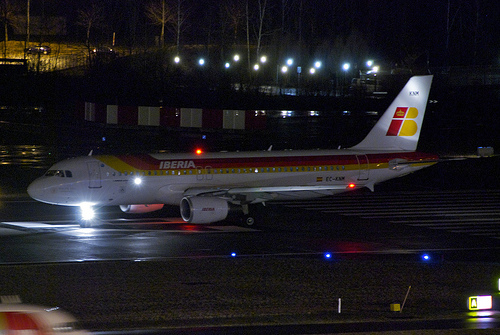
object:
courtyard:
[3, 198, 483, 282]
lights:
[414, 249, 435, 263]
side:
[76, 159, 391, 187]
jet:
[18, 70, 500, 235]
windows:
[341, 165, 347, 171]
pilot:
[49, 169, 64, 178]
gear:
[235, 201, 271, 242]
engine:
[178, 190, 238, 230]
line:
[20, 22, 467, 84]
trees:
[2, 2, 431, 98]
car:
[19, 43, 54, 58]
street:
[12, 49, 104, 71]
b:
[162, 160, 170, 170]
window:
[46, 167, 72, 182]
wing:
[223, 179, 379, 195]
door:
[83, 154, 104, 191]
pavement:
[10, 163, 495, 317]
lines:
[310, 181, 499, 259]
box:
[461, 290, 494, 317]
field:
[8, 265, 500, 329]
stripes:
[106, 154, 398, 178]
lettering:
[148, 158, 219, 179]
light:
[185, 136, 209, 168]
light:
[346, 179, 365, 203]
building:
[71, 97, 276, 133]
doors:
[133, 101, 166, 128]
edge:
[332, 181, 345, 199]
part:
[47, 224, 485, 283]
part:
[337, 143, 390, 186]